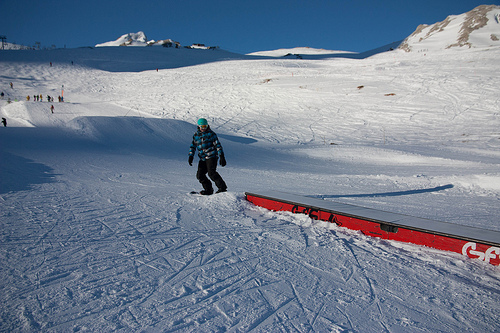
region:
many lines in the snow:
[138, 249, 301, 330]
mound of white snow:
[214, 190, 261, 225]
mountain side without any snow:
[463, 2, 477, 49]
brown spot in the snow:
[336, 77, 398, 117]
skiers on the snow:
[18, 75, 96, 137]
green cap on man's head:
[175, 103, 236, 129]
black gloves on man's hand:
[165, 149, 205, 174]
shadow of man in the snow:
[317, 164, 476, 206]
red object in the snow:
[241, 182, 373, 233]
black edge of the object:
[244, 180, 316, 210]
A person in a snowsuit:
[166, 111, 242, 211]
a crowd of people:
[5, 60, 72, 136]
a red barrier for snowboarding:
[240, 190, 480, 265]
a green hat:
[193, 117, 215, 128]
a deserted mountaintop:
[395, 11, 497, 48]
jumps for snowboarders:
[21, 96, 181, 151]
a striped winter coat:
[178, 134, 230, 156]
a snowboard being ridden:
[185, 187, 247, 200]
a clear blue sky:
[21, 8, 381, 52]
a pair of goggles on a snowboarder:
[186, 123, 213, 128]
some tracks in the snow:
[79, 211, 242, 331]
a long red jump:
[250, 180, 495, 301]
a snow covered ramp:
[239, 165, 484, 258]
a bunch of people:
[16, 81, 98, 116]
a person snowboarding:
[172, 107, 239, 202]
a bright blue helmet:
[189, 113, 214, 133]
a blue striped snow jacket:
[179, 126, 231, 163]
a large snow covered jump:
[36, 101, 178, 160]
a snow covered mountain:
[96, 24, 213, 67]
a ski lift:
[1, 29, 72, 59]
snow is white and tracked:
[40, 182, 275, 327]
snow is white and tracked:
[86, 220, 216, 312]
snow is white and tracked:
[125, 245, 240, 325]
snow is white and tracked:
[153, 235, 288, 327]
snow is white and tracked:
[126, 237, 205, 294]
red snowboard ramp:
[243, 188, 498, 248]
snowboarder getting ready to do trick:
[179, 100, 408, 256]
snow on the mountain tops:
[112, 26, 219, 57]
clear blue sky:
[151, 3, 372, 37]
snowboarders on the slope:
[1, 74, 105, 151]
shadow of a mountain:
[285, 32, 432, 83]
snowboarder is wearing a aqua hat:
[185, 113, 216, 134]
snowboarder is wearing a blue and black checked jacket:
[187, 122, 232, 181]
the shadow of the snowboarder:
[303, 181, 468, 208]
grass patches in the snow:
[240, 67, 408, 110]